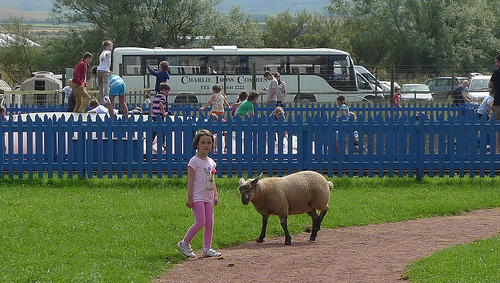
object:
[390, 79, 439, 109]
parked cars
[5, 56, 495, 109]
fence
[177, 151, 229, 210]
pink shirt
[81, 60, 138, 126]
person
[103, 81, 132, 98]
shorts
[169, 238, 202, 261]
shoe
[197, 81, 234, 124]
little girl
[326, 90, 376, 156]
little girl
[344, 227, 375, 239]
ground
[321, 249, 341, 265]
ground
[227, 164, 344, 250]
sheep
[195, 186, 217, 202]
stomach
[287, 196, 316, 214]
stomach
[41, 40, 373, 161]
people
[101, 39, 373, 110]
bus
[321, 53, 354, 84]
window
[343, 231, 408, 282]
ground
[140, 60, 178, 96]
shirt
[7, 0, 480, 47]
field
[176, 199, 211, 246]
leg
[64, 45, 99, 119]
person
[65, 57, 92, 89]
shirt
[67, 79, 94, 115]
khakis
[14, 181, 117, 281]
grass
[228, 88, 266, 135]
person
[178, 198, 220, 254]
pants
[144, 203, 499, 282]
dirt path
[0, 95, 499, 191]
blue fence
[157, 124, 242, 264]
girl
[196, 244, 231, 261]
sneakers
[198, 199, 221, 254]
leg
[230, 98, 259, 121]
shirt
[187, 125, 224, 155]
hair